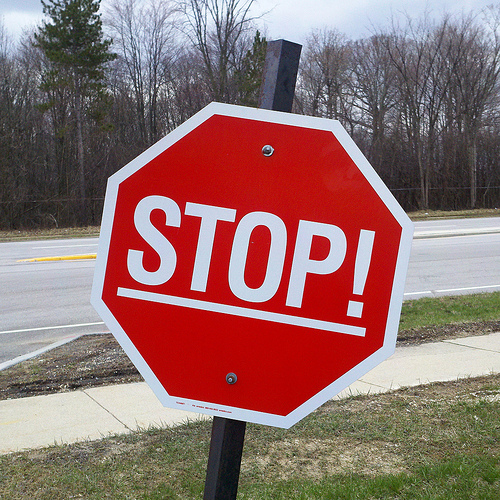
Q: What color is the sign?
A: Red.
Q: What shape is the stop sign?
A: Octagon.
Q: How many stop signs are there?
A: One.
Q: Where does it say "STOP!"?
A: On the stop sign.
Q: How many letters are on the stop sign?
A: Four.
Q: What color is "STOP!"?
A: White.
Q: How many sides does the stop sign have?
A: Eight.